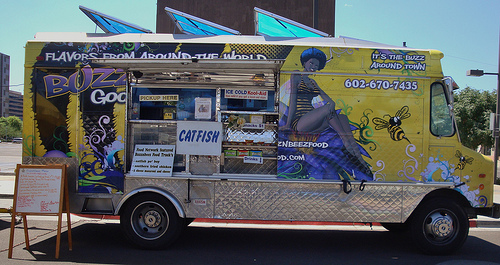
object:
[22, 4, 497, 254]
truck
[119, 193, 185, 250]
rear wheel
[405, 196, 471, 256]
front wheel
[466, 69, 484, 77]
lamp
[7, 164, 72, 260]
menu board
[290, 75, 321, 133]
swimsuit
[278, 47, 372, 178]
woman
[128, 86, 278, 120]
side window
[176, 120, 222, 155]
sign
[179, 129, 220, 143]
writing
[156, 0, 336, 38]
building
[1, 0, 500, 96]
sky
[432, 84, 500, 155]
trees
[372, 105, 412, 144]
bee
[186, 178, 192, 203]
strap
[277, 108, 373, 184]
flower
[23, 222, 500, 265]
shadow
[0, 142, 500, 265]
ground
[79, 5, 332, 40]
vent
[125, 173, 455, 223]
panel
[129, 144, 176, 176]
lower sign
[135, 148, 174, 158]
lower writing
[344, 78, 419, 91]
phone number